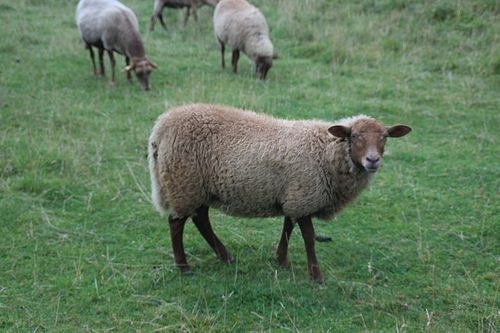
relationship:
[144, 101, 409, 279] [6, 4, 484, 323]
animal in field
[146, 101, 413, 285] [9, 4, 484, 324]
animal in pasture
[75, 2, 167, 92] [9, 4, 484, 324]
sheep in pasture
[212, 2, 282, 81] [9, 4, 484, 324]
sheep in pasture